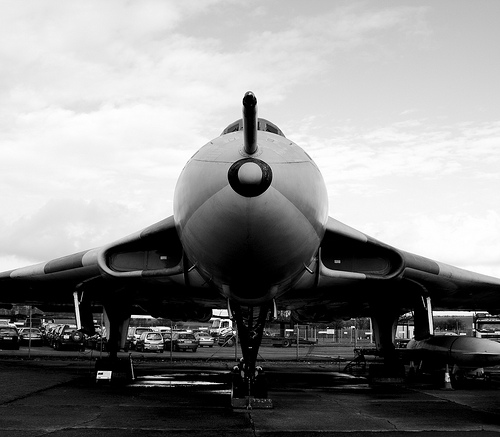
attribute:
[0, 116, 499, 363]
plane — big, resting, large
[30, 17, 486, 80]
sky — grey, black, white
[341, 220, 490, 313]
planeswing — slanted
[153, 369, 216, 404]
fllor — wet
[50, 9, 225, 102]
cumulusclouds — large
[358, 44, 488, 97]
sky — clear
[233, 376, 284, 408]
airplanewheel — in place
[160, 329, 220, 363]
linkfence — metal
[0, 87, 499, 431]
airplaine — big